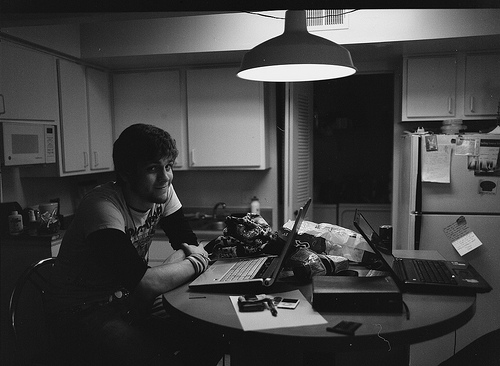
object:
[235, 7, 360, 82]
lighting fixture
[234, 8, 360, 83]
light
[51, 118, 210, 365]
man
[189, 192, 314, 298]
computer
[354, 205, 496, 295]
computer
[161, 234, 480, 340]
table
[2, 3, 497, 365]
kitchen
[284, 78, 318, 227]
door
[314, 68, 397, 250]
door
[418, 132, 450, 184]
magnets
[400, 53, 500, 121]
cabinet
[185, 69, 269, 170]
cabinets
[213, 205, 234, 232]
water